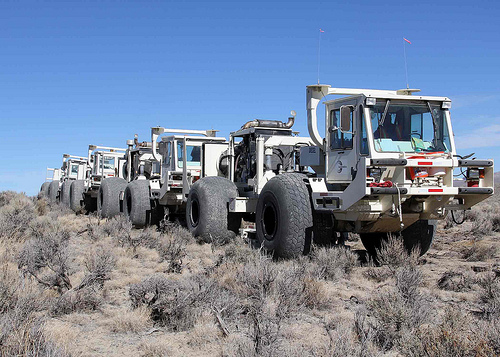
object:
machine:
[185, 29, 496, 263]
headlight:
[366, 97, 377, 106]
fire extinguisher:
[467, 163, 480, 187]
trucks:
[40, 84, 495, 266]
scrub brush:
[15, 240, 72, 290]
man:
[374, 112, 403, 140]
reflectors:
[416, 158, 443, 193]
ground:
[0, 170, 499, 356]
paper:
[411, 136, 425, 153]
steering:
[408, 131, 422, 140]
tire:
[255, 172, 315, 260]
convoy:
[40, 29, 494, 263]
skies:
[0, 1, 499, 196]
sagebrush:
[0, 188, 499, 357]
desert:
[0, 188, 499, 357]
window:
[363, 98, 454, 155]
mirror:
[328, 105, 354, 135]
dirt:
[0, 191, 499, 356]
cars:
[40, 84, 494, 261]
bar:
[385, 152, 458, 182]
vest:
[380, 111, 450, 157]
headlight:
[368, 168, 382, 177]